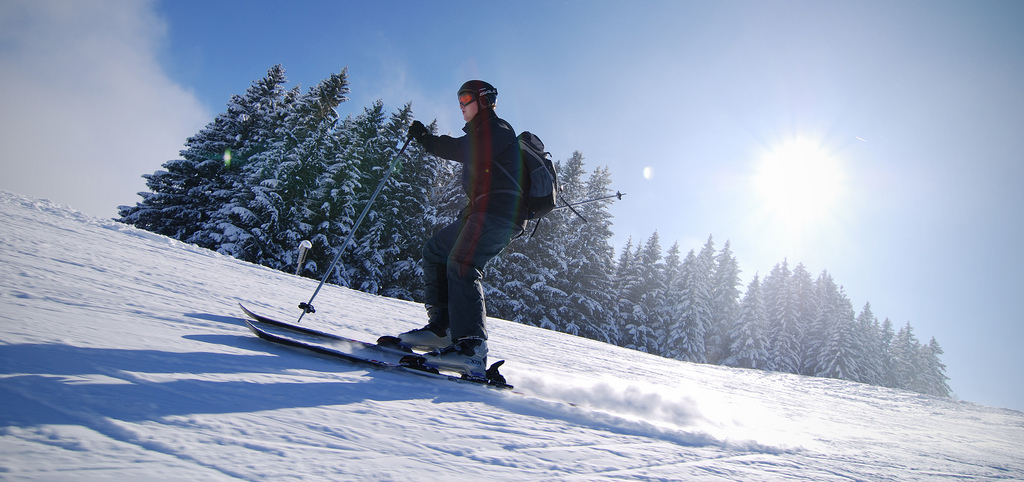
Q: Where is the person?
A: On a ski slope.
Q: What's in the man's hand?
A: A ski pole.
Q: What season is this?
A: Winter.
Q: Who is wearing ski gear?
A: Skier.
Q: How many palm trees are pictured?
A: One.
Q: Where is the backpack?
A: On the back.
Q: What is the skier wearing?
A: A backpack.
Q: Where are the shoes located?
A: In skis.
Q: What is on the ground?
A: Snow.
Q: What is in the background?
A: Trees.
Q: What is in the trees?
A: Snow.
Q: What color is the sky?
A: Blue.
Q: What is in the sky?
A: The sun.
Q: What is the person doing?
A: Skiing.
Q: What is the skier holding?
A: Poles.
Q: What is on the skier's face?
A: Goggles.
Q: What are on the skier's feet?
A: Skis.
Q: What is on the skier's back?
A: A backpack.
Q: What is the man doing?
A: Snow skiing.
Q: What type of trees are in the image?
A: Pine trees.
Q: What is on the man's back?
A: A backpack.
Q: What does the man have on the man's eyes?
A: Goggles.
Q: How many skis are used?
A: Two.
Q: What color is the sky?
A: Blue.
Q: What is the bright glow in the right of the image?
A: The sun.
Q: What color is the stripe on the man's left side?
A: Red.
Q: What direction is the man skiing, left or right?
A: Left.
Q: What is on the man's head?
A: A helmet.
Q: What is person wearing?
A: Backpack.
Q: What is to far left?
A: Tree.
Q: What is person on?
A: Skis.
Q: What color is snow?
A: White.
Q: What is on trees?
A: Snow.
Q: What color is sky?
A: Light blue.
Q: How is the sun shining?
A: Bright.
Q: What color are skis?
A: Black.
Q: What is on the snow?
A: Dark shadow.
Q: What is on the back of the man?
A: Backpack.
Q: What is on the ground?
A: Snow.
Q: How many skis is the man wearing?
A: Two.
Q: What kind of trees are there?
A: Evergreen.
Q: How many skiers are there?
A: One.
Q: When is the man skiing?
A: Winter day.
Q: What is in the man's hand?
A: Pole.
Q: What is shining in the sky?
A: Sun.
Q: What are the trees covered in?
A: Snow.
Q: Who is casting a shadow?
A: Skier.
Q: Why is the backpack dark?
A: Shadow.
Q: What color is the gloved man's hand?
A: Black.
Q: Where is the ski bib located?
A: Head.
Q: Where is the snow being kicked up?
A: By skis.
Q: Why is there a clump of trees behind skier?
A: Shade.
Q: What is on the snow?
A: Shadows.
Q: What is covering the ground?
A: Snow.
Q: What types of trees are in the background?
A: Pine trees.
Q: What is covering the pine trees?
A: Snow.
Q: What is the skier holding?
A: Ski pole.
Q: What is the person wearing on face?
A: Goggles.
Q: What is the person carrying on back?
A: Backpack.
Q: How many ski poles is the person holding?
A: One.